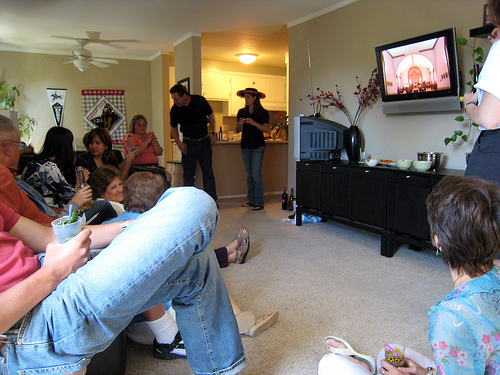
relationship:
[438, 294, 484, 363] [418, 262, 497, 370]
pattern on shirt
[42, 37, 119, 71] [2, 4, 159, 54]
ceiling fan on ceiling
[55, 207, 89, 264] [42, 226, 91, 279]
cup in hand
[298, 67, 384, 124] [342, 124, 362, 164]
flowers sitting in vase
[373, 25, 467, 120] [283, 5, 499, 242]
television mounted to wall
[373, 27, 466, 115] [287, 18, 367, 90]
television hanging on wall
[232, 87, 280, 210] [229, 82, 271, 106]
woman wearing a hat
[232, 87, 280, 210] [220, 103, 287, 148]
woman wearing a shirt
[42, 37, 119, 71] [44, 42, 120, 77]
ceiling fan mounted to ceiling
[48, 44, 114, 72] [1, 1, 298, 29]
ceiling fan mounted to ceiling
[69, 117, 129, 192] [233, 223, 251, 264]
woman wearing sandals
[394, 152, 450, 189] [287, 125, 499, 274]
bowls displayed on a counter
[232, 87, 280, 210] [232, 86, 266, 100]
woman wearing a hat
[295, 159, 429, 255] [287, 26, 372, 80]
cabinet leaning against a wall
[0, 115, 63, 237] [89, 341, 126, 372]
man sitting in chair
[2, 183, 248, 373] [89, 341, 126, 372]
man sitting in chair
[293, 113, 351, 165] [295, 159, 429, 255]
tv sitting on cabinet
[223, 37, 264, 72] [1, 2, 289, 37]
ceiling light mounted on ceiling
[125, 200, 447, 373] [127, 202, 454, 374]
ivory rugs installed on floor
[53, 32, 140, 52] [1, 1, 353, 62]
fan shadow portrayed on ceiling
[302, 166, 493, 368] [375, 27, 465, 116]
woman watching television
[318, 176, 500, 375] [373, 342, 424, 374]
woman holding beverage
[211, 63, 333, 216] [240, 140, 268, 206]
woman wearing pants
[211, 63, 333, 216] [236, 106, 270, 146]
woman wearing a shirt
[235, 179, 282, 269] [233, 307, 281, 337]
sandals worn on feet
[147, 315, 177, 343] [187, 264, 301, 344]
socks worn with sandal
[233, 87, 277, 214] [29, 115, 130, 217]
friend standing in living room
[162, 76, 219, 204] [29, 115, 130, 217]
friend standing in living room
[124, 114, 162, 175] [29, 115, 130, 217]
friend sitting in living room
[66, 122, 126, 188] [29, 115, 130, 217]
friend sitting in living room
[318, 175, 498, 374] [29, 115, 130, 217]
friend sitting in living room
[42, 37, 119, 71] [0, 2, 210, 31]
ceiling fan mounted on ceiling